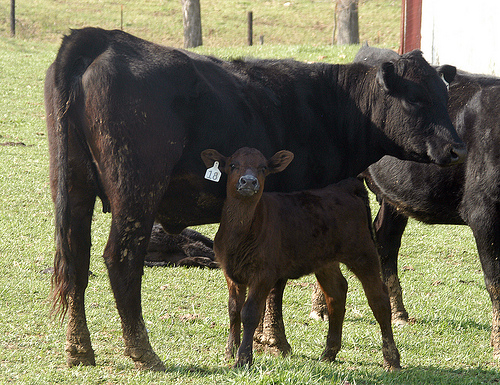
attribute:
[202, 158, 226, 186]
tag — numbered, 18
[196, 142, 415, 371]
calf — standing, looking, baby, brown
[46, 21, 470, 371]
cow — adult, big, standing, large, black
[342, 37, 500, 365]
cow — standing, black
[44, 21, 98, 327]
tail — hanging, long, black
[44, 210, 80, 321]
strands — pointy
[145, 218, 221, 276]
animal — laying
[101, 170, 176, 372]
leg — black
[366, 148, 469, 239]
underside — curved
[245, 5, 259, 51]
post — brown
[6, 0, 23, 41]
post — brown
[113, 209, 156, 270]
knobs — irregular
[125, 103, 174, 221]
protrusions — irregular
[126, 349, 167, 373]
hoof — dirty, covered, muddy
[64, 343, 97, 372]
hoof — dirty, covered, muddy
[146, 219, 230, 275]
cow — laying, reclining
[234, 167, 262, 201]
nose — black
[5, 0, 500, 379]
grass — lush, green, short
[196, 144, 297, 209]
head — looking, forward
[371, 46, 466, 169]
head — obstructing, black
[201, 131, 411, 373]
cow — standing, black, baby